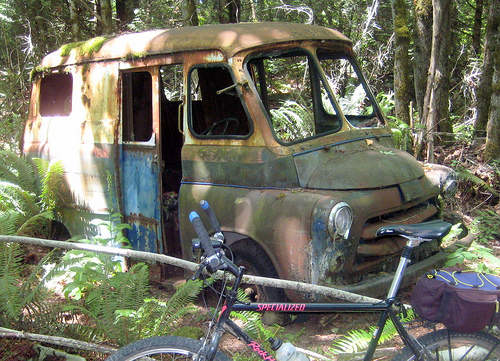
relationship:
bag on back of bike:
[411, 270, 498, 324] [119, 186, 489, 359]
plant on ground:
[49, 241, 221, 351] [2, 134, 499, 357]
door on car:
[116, 40, 162, 280] [22, 21, 475, 327]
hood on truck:
[268, 136, 468, 210] [0, 0, 474, 300]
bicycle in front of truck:
[105, 198, 500, 359] [19, 0, 482, 337]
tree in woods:
[385, 0, 464, 212] [0, 0, 499, 359]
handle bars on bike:
[161, 166, 291, 341] [119, 186, 489, 359]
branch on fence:
[7, 308, 128, 359] [9, 191, 464, 359]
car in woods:
[9, 5, 474, 295] [7, 2, 493, 198]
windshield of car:
[243, 22, 394, 179] [15, 25, 483, 335]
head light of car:
[319, 196, 368, 258] [22, 21, 475, 327]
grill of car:
[325, 172, 463, 307] [9, 0, 479, 338]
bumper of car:
[298, 237, 488, 333] [15, 25, 483, 335]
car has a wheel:
[22, 21, 475, 327] [226, 244, 266, 287]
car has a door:
[22, 21, 475, 327] [122, 69, 172, 254]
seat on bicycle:
[376, 220, 453, 239] [183, 244, 422, 355]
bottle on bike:
[268, 337, 311, 360] [157, 212, 380, 359]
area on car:
[350, 183, 416, 210] [188, 80, 398, 242]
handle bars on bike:
[186, 210, 217, 260] [141, 193, 463, 345]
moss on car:
[21, 33, 86, 64] [23, 20, 195, 140]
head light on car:
[324, 201, 355, 243] [195, 89, 313, 199]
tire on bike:
[131, 317, 194, 342] [184, 242, 380, 342]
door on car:
[116, 67, 162, 280] [22, 21, 475, 327]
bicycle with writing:
[108, 193, 496, 359] [253, 298, 310, 314]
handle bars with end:
[186, 210, 217, 260] [183, 209, 201, 224]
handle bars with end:
[186, 210, 217, 260] [199, 196, 214, 214]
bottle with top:
[264, 333, 341, 359] [264, 333, 284, 354]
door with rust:
[116, 67, 162, 280] [116, 210, 156, 231]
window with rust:
[176, 53, 252, 147] [174, 57, 219, 71]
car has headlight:
[22, 21, 475, 327] [325, 200, 358, 246]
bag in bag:
[410, 268, 500, 334] [405, 264, 495, 334]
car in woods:
[22, 21, 475, 327] [3, 3, 492, 355]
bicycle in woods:
[105, 198, 500, 359] [3, 3, 492, 355]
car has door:
[22, 21, 475, 327] [116, 67, 162, 280]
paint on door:
[120, 148, 166, 253] [114, 54, 172, 272]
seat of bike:
[377, 214, 456, 246] [119, 186, 489, 359]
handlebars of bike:
[177, 193, 242, 285] [103, 195, 493, 358]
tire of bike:
[105, 334, 230, 361] [119, 186, 489, 359]